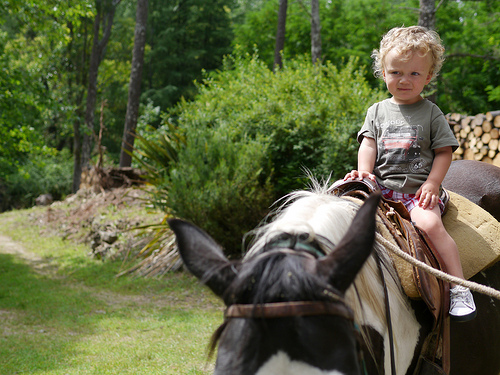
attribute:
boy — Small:
[331, 19, 482, 332]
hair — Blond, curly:
[368, 23, 445, 79]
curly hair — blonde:
[372, 24, 446, 94]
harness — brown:
[220, 292, 352, 324]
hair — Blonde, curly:
[372, 25, 444, 96]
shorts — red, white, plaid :
[375, 182, 447, 209]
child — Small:
[345, 22, 477, 319]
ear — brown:
[332, 191, 389, 288]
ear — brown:
[172, 211, 233, 296]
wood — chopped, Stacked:
[445, 109, 498, 176]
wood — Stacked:
[441, 110, 498, 165]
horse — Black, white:
[162, 158, 498, 373]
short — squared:
[365, 177, 444, 212]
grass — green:
[35, 261, 182, 352]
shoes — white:
[445, 283, 476, 322]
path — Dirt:
[2, 222, 212, 343]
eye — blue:
[388, 67, 401, 76]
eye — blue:
[408, 65, 420, 76]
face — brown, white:
[222, 320, 346, 372]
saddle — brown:
[324, 170, 488, 331]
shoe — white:
[448, 282, 473, 317]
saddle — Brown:
[336, 172, 456, 315]